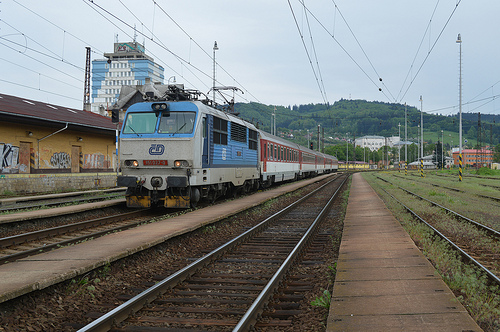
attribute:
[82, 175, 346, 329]
train tracks — light grey, metal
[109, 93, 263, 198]
train engine — blue, grey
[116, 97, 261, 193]
front car — white, blue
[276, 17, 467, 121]
wires — dark black, interconnected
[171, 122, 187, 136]
wiper — black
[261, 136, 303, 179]
train car — red, white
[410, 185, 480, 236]
grass — patchy, green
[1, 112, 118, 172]
building — yellow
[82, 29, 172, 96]
building — white colored, tall, blue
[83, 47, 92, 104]
pole — metal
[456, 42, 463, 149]
pole — metal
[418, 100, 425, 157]
pole — metal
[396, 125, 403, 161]
pole — metal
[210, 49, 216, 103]
pole — metal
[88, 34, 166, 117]
building — blue, white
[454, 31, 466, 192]
post — black, yellow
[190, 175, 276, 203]
wheels — black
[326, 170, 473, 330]
pathway — light brown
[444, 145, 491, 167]
building — red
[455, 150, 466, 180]
pole — striped, yellow, black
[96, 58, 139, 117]
design — white, pyramid